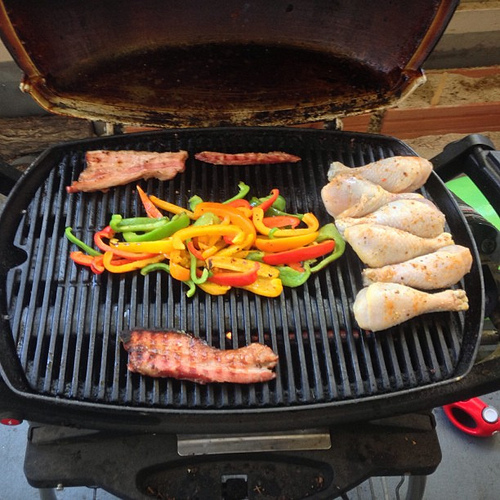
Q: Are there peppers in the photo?
A: Yes, there are peppers.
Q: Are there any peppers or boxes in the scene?
A: Yes, there are peppers.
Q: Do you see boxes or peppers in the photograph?
A: Yes, there are peppers.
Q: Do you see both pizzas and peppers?
A: No, there are peppers but no pizzas.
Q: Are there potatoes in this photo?
A: No, there are no potatoes.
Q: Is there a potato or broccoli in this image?
A: No, there are no potatoes or broccoli.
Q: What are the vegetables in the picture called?
A: The vegetables are peppers.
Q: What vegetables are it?
A: The vegetables are peppers.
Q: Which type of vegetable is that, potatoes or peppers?
A: These are peppers.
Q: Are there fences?
A: No, there are no fences.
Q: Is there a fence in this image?
A: No, there are no fences.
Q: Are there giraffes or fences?
A: No, there are no fences or giraffes.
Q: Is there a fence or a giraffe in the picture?
A: No, there are no fences or giraffes.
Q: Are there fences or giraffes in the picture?
A: No, there are no fences or giraffes.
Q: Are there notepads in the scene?
A: No, there are no notepads.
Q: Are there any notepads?
A: No, there are no notepads.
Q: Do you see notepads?
A: No, there are no notepads.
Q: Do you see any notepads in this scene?
A: No, there are no notepads.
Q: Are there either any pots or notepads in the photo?
A: No, there are no notepads or pots.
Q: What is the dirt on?
A: The dirt is on the steps.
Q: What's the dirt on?
A: The dirt is on the steps.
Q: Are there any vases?
A: No, there are no vases.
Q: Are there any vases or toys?
A: No, there are no vases or toys.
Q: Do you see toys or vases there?
A: No, there are no vases or toys.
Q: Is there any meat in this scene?
A: Yes, there is meat.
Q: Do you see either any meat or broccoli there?
A: Yes, there is meat.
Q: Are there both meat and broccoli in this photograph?
A: No, there is meat but no broccoli.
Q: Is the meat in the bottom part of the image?
A: Yes, the meat is in the bottom of the image.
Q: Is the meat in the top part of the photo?
A: No, the meat is in the bottom of the image.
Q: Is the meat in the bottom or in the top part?
A: The meat is in the bottom of the image.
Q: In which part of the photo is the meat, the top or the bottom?
A: The meat is in the bottom of the image.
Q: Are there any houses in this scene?
A: No, there are no houses.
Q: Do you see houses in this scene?
A: No, there are no houses.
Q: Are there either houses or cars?
A: No, there are no houses or cars.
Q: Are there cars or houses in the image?
A: No, there are no houses or cars.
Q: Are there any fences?
A: No, there are no fences.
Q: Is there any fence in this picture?
A: No, there are no fences.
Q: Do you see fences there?
A: No, there are no fences.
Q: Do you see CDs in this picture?
A: No, there are no cds.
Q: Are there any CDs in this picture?
A: No, there are no cds.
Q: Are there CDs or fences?
A: No, there are no CDs or fences.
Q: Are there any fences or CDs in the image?
A: No, there are no CDs or fences.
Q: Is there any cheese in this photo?
A: No, there is no cheese.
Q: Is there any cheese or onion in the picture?
A: No, there are no cheese or onions.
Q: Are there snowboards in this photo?
A: No, there are no snowboards.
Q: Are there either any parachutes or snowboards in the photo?
A: No, there are no snowboards or parachutes.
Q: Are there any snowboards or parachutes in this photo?
A: No, there are no snowboards or parachutes.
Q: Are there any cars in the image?
A: No, there are no cars.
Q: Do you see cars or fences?
A: No, there are no cars or fences.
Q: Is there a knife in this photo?
A: No, there are no knives.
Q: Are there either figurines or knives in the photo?
A: No, there are no knives or figurines.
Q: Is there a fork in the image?
A: No, there are no forks.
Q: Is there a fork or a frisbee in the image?
A: No, there are no forks or frisbees.